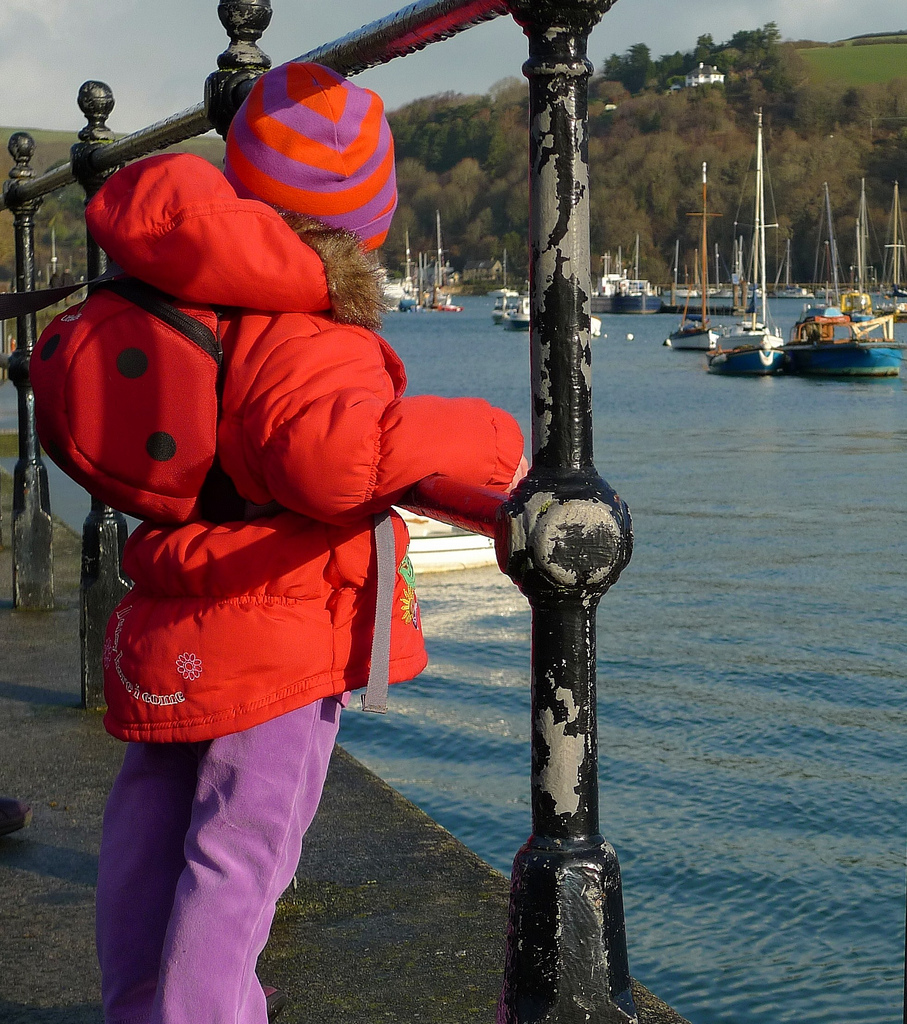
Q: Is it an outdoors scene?
A: Yes, it is outdoors.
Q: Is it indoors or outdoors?
A: It is outdoors.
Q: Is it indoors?
A: No, it is outdoors.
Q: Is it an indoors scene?
A: No, it is outdoors.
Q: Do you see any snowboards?
A: No, there are no snowboards.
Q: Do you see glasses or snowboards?
A: No, there are no snowboards or glasses.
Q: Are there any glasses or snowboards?
A: No, there are no snowboards or glasses.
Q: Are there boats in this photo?
A: Yes, there is a boat.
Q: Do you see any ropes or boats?
A: Yes, there is a boat.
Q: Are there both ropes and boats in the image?
A: No, there is a boat but no ropes.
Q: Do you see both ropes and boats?
A: No, there is a boat but no ropes.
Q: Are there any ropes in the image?
A: No, there are no ropes.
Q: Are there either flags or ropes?
A: No, there are no ropes or flags.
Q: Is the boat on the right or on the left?
A: The boat is on the right of the image.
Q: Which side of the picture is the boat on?
A: The boat is on the right of the image.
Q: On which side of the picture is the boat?
A: The boat is on the right of the image.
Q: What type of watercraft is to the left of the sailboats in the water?
A: The watercraft is a boat.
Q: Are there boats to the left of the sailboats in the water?
A: Yes, there is a boat to the left of the sailboats.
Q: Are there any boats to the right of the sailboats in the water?
A: No, the boat is to the left of the sailboats.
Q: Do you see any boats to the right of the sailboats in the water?
A: No, the boat is to the left of the sailboats.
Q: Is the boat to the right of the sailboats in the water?
A: No, the boat is to the left of the sailboats.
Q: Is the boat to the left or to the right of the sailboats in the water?
A: The boat is to the left of the sailboats.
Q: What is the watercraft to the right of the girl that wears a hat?
A: The watercraft is a boat.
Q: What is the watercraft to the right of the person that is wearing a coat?
A: The watercraft is a boat.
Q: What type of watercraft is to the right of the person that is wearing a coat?
A: The watercraft is a boat.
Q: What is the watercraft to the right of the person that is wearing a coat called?
A: The watercraft is a boat.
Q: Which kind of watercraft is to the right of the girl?
A: The watercraft is a boat.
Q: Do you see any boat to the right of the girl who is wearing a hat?
A: Yes, there is a boat to the right of the girl.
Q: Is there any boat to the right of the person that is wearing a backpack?
A: Yes, there is a boat to the right of the girl.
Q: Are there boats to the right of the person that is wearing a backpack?
A: Yes, there is a boat to the right of the girl.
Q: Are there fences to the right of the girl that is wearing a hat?
A: No, there is a boat to the right of the girl.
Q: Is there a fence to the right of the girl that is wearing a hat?
A: No, there is a boat to the right of the girl.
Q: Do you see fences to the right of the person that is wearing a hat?
A: No, there is a boat to the right of the girl.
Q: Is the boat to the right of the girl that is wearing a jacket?
A: Yes, the boat is to the right of the girl.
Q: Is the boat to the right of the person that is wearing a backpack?
A: Yes, the boat is to the right of the girl.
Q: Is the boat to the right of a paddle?
A: No, the boat is to the right of the girl.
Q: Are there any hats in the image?
A: Yes, there is a hat.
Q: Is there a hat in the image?
A: Yes, there is a hat.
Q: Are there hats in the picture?
A: Yes, there is a hat.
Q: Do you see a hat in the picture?
A: Yes, there is a hat.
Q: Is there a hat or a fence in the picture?
A: Yes, there is a hat.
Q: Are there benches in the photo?
A: No, there are no benches.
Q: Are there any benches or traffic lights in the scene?
A: No, there are no benches or traffic lights.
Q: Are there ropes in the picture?
A: No, there are no ropes.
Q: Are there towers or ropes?
A: No, there are no ropes or towers.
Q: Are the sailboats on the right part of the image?
A: Yes, the sailboats are on the right of the image.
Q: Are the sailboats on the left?
A: No, the sailboats are on the right of the image.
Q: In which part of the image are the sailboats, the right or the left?
A: The sailboats are on the right of the image.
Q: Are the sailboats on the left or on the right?
A: The sailboats are on the right of the image.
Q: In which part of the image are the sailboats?
A: The sailboats are on the right of the image.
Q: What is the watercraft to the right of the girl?
A: The watercraft is sailboats.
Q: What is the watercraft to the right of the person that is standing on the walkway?
A: The watercraft is sailboats.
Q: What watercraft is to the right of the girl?
A: The watercraft is sailboats.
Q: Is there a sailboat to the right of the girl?
A: Yes, there are sailboats to the right of the girl.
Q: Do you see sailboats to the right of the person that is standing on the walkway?
A: Yes, there are sailboats to the right of the girl.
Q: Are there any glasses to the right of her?
A: No, there are sailboats to the right of the girl.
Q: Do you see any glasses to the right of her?
A: No, there are sailboats to the right of the girl.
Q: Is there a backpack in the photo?
A: Yes, there is a backpack.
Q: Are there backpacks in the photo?
A: Yes, there is a backpack.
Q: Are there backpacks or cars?
A: Yes, there is a backpack.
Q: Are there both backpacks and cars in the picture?
A: No, there is a backpack but no cars.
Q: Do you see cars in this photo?
A: No, there are no cars.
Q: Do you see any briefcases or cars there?
A: No, there are no cars or briefcases.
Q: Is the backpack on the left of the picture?
A: Yes, the backpack is on the left of the image.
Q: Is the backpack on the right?
A: No, the backpack is on the left of the image.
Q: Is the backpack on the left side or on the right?
A: The backpack is on the left of the image.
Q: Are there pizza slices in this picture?
A: No, there are no pizza slices.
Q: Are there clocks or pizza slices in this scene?
A: No, there are no pizza slices or clocks.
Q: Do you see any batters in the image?
A: No, there are no batters.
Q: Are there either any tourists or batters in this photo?
A: No, there are no batters or tourists.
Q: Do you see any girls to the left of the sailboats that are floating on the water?
A: Yes, there is a girl to the left of the sailboats.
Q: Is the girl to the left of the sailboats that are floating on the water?
A: Yes, the girl is to the left of the sailboats.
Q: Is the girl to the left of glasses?
A: No, the girl is to the left of the sailboats.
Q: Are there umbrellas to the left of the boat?
A: No, there is a girl to the left of the boat.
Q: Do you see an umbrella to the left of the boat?
A: No, there is a girl to the left of the boat.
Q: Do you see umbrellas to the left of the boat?
A: No, there is a girl to the left of the boat.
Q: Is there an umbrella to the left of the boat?
A: No, there is a girl to the left of the boat.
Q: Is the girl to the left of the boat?
A: Yes, the girl is to the left of the boat.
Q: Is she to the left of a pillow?
A: No, the girl is to the left of the boat.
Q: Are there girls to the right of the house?
A: No, the girl is to the left of the house.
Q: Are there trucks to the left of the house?
A: No, there is a girl to the left of the house.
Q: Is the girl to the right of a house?
A: No, the girl is to the left of a house.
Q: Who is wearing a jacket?
A: The girl is wearing a jacket.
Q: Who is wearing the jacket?
A: The girl is wearing a jacket.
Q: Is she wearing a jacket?
A: Yes, the girl is wearing a jacket.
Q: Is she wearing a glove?
A: No, the girl is wearing a jacket.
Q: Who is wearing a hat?
A: The girl is wearing a hat.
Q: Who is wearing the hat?
A: The girl is wearing a hat.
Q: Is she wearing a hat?
A: Yes, the girl is wearing a hat.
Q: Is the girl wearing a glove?
A: No, the girl is wearing a hat.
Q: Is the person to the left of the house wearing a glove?
A: No, the girl is wearing a hat.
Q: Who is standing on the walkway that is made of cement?
A: The girl is standing on the walkway.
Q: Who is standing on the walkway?
A: The girl is standing on the walkway.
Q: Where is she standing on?
A: The girl is standing on the walkway.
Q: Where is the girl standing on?
A: The girl is standing on the walkway.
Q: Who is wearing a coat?
A: The girl is wearing a coat.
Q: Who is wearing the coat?
A: The girl is wearing a coat.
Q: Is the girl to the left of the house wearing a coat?
A: Yes, the girl is wearing a coat.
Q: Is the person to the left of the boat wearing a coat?
A: Yes, the girl is wearing a coat.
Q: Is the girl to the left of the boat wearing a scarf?
A: No, the girl is wearing a coat.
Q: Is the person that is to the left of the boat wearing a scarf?
A: No, the girl is wearing a coat.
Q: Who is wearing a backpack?
A: The girl is wearing a backpack.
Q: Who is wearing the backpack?
A: The girl is wearing a backpack.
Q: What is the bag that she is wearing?
A: The bag is a backpack.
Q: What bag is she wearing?
A: The girl is wearing a backpack.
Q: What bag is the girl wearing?
A: The girl is wearing a backpack.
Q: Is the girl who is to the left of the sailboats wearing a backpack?
A: Yes, the girl is wearing a backpack.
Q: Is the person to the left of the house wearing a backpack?
A: Yes, the girl is wearing a backpack.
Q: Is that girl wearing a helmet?
A: No, the girl is wearing a backpack.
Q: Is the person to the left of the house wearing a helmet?
A: No, the girl is wearing a backpack.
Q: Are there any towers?
A: No, there are no towers.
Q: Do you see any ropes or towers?
A: No, there are no towers or ropes.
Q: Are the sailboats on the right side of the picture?
A: Yes, the sailboats are on the right of the image.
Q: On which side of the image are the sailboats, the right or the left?
A: The sailboats are on the right of the image.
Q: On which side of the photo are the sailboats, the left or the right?
A: The sailboats are on the right of the image.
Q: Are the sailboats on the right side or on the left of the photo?
A: The sailboats are on the right of the image.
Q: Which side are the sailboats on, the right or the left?
A: The sailboats are on the right of the image.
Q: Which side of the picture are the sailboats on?
A: The sailboats are on the right of the image.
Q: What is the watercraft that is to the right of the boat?
A: The watercraft is sailboats.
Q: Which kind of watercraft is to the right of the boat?
A: The watercraft is sailboats.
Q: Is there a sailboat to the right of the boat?
A: Yes, there are sailboats to the right of the boat.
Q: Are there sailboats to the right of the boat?
A: Yes, there are sailboats to the right of the boat.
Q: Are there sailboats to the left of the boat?
A: No, the sailboats are to the right of the boat.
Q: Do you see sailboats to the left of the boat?
A: No, the sailboats are to the right of the boat.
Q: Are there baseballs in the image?
A: No, there are no baseballs.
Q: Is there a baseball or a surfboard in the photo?
A: No, there are no baseballs or surfboards.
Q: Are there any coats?
A: Yes, there is a coat.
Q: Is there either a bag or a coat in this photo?
A: Yes, there is a coat.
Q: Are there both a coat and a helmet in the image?
A: No, there is a coat but no helmets.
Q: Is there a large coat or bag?
A: Yes, there is a large coat.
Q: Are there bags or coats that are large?
A: Yes, the coat is large.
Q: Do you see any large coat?
A: Yes, there is a large coat.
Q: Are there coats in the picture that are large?
A: Yes, there is a coat that is large.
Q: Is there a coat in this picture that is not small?
A: Yes, there is a large coat.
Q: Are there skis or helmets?
A: No, there are no helmets or skis.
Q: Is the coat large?
A: Yes, the coat is large.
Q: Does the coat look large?
A: Yes, the coat is large.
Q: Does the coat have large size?
A: Yes, the coat is large.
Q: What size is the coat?
A: The coat is large.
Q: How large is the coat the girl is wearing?
A: The coat is large.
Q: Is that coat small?
A: No, the coat is large.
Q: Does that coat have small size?
A: No, the coat is large.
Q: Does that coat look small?
A: No, the coat is large.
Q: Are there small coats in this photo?
A: No, there is a coat but it is large.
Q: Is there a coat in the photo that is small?
A: No, there is a coat but it is large.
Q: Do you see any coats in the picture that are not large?
A: No, there is a coat but it is large.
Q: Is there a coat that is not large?
A: No, there is a coat but it is large.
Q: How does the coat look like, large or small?
A: The coat is large.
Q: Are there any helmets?
A: No, there are no helmets.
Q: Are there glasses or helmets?
A: No, there are no helmets or glasses.